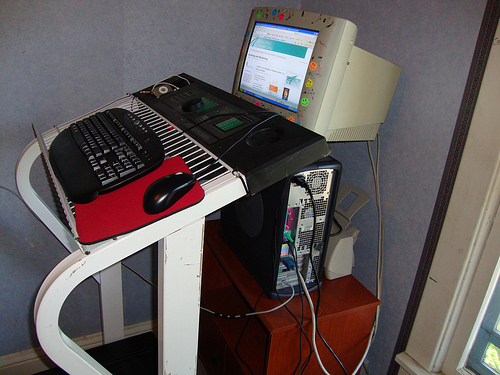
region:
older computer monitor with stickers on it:
[228, 0, 389, 150]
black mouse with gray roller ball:
[144, 170, 199, 220]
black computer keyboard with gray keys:
[53, 110, 169, 199]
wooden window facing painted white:
[413, 81, 490, 372]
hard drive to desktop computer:
[252, 155, 342, 323]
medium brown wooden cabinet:
[202, 214, 366, 373]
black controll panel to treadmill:
[139, 65, 326, 197]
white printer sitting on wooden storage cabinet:
[326, 183, 379, 292]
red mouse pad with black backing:
[72, 148, 205, 240]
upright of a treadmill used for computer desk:
[17, 89, 338, 374]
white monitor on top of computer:
[231, 5, 403, 144]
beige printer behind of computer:
[324, 182, 374, 284]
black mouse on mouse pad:
[140, 170, 197, 215]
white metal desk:
[14, 90, 249, 372]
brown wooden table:
[205, 215, 383, 372]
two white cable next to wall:
[293, 135, 384, 372]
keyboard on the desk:
[47, 107, 167, 204]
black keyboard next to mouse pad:
[45, 105, 160, 200]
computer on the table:
[217, 150, 342, 295]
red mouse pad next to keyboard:
[72, 155, 204, 246]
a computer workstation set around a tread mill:
[2, 3, 497, 365]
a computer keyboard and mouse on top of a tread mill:
[22, 59, 336, 251]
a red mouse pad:
[60, 153, 210, 249]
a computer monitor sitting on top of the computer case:
[235, 0, 398, 298]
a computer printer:
[318, 170, 371, 298]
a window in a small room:
[407, 2, 495, 372]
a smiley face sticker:
[307, 56, 319, 71]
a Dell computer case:
[224, 163, 340, 298]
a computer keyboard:
[28, 104, 167, 199]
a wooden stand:
[193, 219, 386, 371]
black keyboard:
[44, 101, 179, 201]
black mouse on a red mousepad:
[74, 152, 214, 244]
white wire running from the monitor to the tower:
[275, 128, 406, 373]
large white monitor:
[232, 6, 418, 173]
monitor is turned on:
[222, 7, 424, 152]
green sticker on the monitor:
[297, 95, 313, 110]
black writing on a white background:
[239, 70, 271, 89]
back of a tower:
[279, 173, 341, 312]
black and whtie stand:
[14, 70, 317, 374]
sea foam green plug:
[283, 225, 295, 244]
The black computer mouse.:
[140, 165, 197, 210]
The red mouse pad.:
[70, 148, 206, 240]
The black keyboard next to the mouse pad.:
[47, 113, 162, 189]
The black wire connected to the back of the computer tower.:
[284, 175, 325, 247]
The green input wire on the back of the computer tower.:
[282, 228, 298, 248]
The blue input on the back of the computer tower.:
[281, 253, 298, 270]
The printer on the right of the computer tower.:
[328, 173, 365, 285]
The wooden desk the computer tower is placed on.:
[203, 218, 375, 371]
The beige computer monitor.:
[230, 6, 405, 146]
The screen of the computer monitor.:
[234, 19, 313, 105]